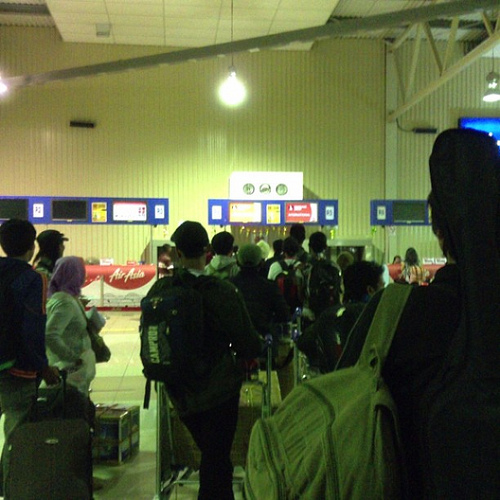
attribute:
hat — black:
[169, 217, 209, 259]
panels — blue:
[207, 199, 339, 227]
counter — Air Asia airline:
[78, 257, 174, 301]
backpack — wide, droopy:
[254, 242, 412, 499]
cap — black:
[167, 217, 212, 257]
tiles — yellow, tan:
[108, 348, 137, 399]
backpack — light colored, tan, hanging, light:
[236, 280, 415, 499]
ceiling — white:
[44, 0, 340, 52]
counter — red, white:
[75, 259, 153, 309]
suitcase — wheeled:
[1, 373, 115, 495]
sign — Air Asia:
[99, 262, 187, 314]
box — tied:
[84, 394, 149, 469]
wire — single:
[228, 0, 235, 75]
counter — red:
[387, 263, 444, 282]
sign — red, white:
[89, 264, 151, 310]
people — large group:
[316, 222, 357, 314]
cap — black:
[153, 216, 225, 263]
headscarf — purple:
[44, 252, 86, 297]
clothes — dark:
[139, 260, 260, 498]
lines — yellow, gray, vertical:
[8, 20, 417, 261]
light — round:
[209, 68, 258, 109]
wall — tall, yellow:
[6, 19, 493, 335]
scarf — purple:
[51, 251, 85, 298]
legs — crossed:
[168, 384, 246, 496]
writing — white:
[137, 319, 167, 372]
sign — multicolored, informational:
[203, 198, 339, 227]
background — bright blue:
[208, 201, 342, 225]